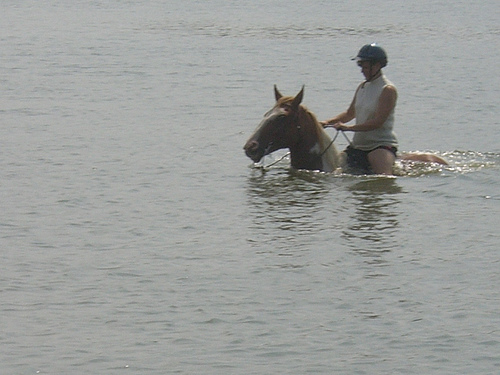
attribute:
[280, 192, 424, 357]
wave — part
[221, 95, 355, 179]
horse — part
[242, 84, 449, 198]
horse — wet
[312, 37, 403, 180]
rider — wet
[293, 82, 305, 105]
ear — short, horse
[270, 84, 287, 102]
ear — short, horse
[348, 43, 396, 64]
cap — blue, colored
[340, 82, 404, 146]
elbow — left elbow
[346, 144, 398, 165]
pant — short, black, colored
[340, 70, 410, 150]
shirt — part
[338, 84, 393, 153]
top — white, sleeveless, light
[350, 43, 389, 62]
helmet — safety helmet, dark colored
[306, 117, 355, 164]
rope — long, narrow, navigating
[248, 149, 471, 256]
wavy water — black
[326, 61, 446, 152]
shirt — white 